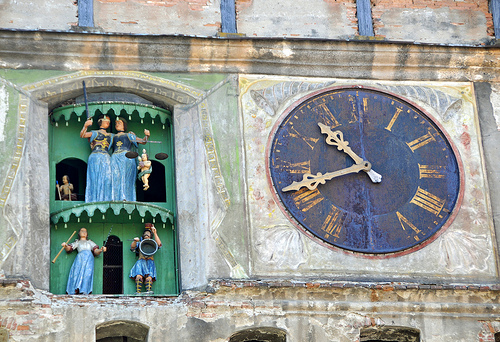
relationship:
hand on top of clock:
[280, 165, 374, 200] [263, 89, 455, 250]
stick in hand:
[56, 226, 73, 263] [280, 165, 374, 200]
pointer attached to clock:
[317, 120, 379, 181] [263, 89, 455, 250]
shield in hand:
[130, 236, 169, 256] [280, 165, 374, 200]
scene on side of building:
[33, 36, 226, 213] [72, 34, 461, 335]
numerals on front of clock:
[327, 105, 412, 135] [263, 89, 455, 250]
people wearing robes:
[91, 164, 132, 199] [83, 124, 140, 202]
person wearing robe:
[57, 238, 117, 262] [134, 262, 154, 283]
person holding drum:
[57, 238, 117, 262] [96, 246, 106, 253]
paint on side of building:
[207, 18, 265, 91] [72, 34, 461, 335]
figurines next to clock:
[29, 74, 169, 305] [263, 89, 455, 250]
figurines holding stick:
[29, 74, 169, 305] [56, 226, 73, 263]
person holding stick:
[57, 226, 104, 296] [56, 226, 73, 263]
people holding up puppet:
[81, 117, 111, 200] [127, 149, 158, 188]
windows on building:
[91, 236, 148, 318] [72, 34, 461, 335]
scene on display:
[33, 36, 226, 213] [35, 285, 194, 313]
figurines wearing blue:
[29, 74, 169, 305] [60, 152, 131, 195]